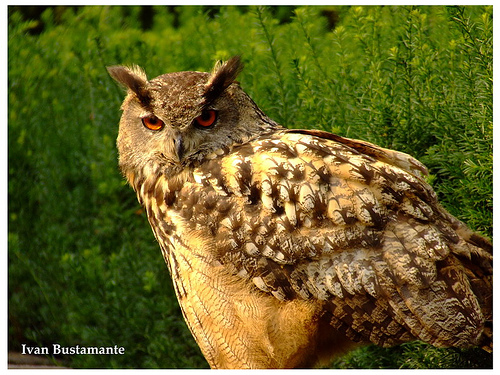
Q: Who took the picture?
A: Ivan bustamante.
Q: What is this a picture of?
A: Owl.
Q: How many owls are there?
A: 1.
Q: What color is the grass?
A: Green.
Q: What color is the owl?
A: Brown.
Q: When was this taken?
A: Daytime.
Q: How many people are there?
A: 0.